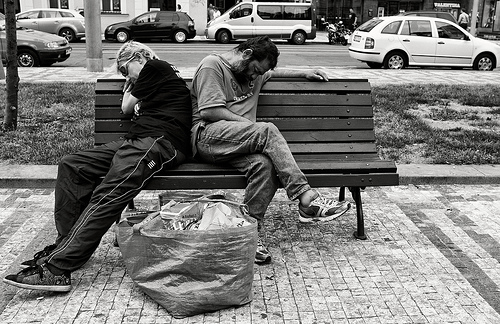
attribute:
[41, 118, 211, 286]
pants — striped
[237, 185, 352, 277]
shoes — tennis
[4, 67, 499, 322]
ground — brick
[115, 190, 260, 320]
bag — plastic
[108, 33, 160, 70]
hair — blond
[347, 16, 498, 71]
car — white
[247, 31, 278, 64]
hair — dark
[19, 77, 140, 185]
grass — short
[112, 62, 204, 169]
shirt — black